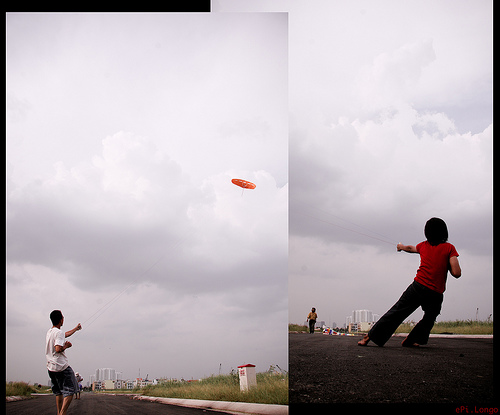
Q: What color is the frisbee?
A: Orange.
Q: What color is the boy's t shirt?
A: White.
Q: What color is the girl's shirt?
A: Red.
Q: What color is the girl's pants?
A: Black.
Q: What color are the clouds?
A: Gray.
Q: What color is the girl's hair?
A: Black.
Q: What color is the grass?
A: Green.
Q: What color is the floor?
A: Gray.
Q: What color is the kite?
A: Orange.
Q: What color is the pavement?
A: Black.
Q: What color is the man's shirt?
A: White.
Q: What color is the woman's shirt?
A: Red.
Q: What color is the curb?
A: White.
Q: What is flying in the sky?
A: Kite.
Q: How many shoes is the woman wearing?
A: Zero.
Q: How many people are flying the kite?
A: Two.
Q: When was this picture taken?
A: Daytime.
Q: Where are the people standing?
A: On a street.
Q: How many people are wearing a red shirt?
A: One.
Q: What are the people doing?
A: Flying kites.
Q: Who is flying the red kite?
A: A man.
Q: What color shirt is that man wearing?
A: White.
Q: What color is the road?
A: Black.